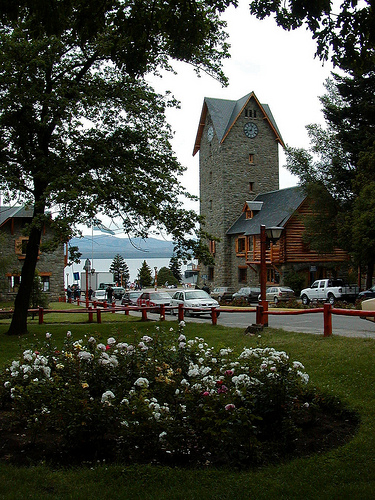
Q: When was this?
A: Daytime.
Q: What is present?
A: Buildings.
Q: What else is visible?
A: Cars.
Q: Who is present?
A: Nobody.